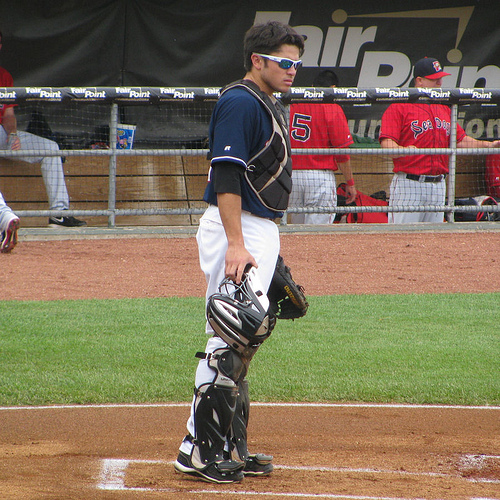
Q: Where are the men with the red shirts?
A: In the dugout.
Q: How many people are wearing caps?
A: One.